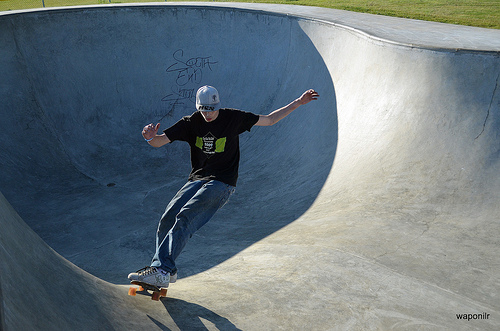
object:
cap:
[194, 84, 221, 115]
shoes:
[125, 265, 171, 290]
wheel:
[139, 285, 148, 292]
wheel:
[149, 290, 161, 302]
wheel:
[159, 287, 168, 297]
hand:
[139, 120, 162, 142]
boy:
[126, 82, 324, 289]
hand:
[296, 87, 321, 106]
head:
[192, 83, 224, 123]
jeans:
[145, 176, 238, 272]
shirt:
[163, 109, 262, 187]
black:
[217, 112, 243, 131]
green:
[433, 3, 484, 22]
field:
[1, 0, 499, 28]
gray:
[421, 74, 455, 131]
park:
[0, 2, 500, 331]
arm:
[239, 96, 304, 128]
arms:
[147, 115, 192, 148]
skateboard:
[127, 280, 173, 302]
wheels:
[125, 287, 137, 297]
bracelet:
[143, 136, 156, 142]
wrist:
[143, 133, 158, 144]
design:
[192, 131, 228, 154]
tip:
[129, 279, 150, 285]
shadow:
[0, 5, 344, 284]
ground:
[197, 234, 356, 295]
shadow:
[139, 288, 237, 331]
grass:
[0, 0, 498, 29]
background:
[2, 1, 495, 63]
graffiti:
[163, 47, 220, 84]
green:
[216, 140, 223, 148]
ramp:
[14, 5, 295, 198]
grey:
[200, 90, 213, 104]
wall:
[331, 51, 498, 219]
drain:
[105, 181, 118, 187]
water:
[102, 179, 120, 189]